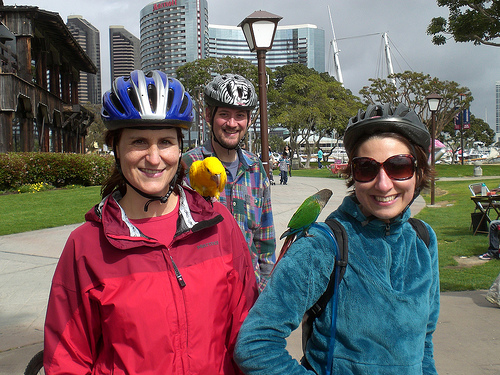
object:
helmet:
[99, 65, 199, 131]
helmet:
[199, 69, 260, 112]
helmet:
[340, 100, 430, 161]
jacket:
[37, 184, 259, 374]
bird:
[186, 153, 230, 204]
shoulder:
[186, 192, 234, 226]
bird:
[266, 187, 336, 278]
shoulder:
[296, 212, 351, 259]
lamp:
[236, 7, 283, 181]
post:
[254, 54, 274, 177]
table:
[330, 161, 352, 174]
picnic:
[325, 157, 350, 178]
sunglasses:
[348, 151, 421, 183]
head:
[339, 129, 428, 221]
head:
[113, 124, 181, 195]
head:
[203, 98, 252, 150]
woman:
[229, 100, 439, 375]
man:
[176, 71, 279, 294]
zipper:
[160, 246, 187, 374]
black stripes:
[228, 97, 236, 107]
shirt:
[173, 140, 275, 291]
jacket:
[233, 193, 441, 375]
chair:
[467, 180, 499, 235]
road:
[0, 176, 499, 374]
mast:
[379, 33, 397, 89]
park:
[0, 150, 499, 374]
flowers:
[16, 187, 24, 193]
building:
[137, 1, 327, 150]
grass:
[270, 164, 500, 291]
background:
[0, 0, 499, 374]